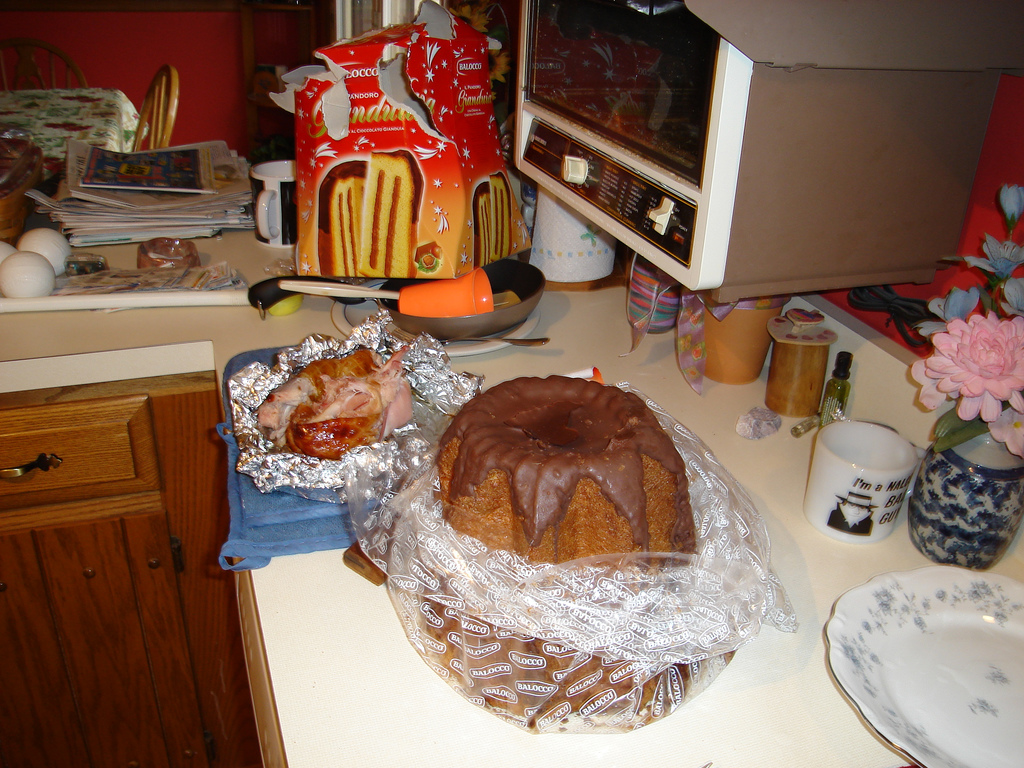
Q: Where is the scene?
A: In a kitchen.